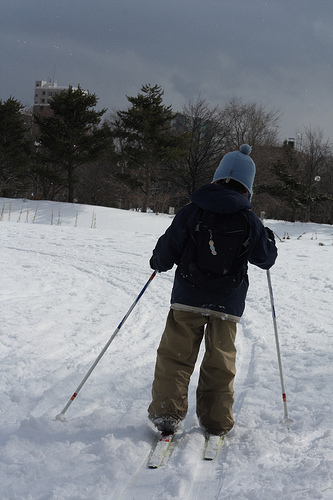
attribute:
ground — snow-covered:
[8, 245, 118, 500]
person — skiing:
[155, 129, 300, 479]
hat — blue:
[220, 147, 261, 187]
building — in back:
[54, 69, 307, 218]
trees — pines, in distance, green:
[17, 92, 320, 230]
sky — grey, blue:
[43, 14, 237, 76]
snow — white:
[20, 423, 331, 487]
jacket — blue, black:
[136, 147, 251, 302]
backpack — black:
[172, 191, 257, 299]